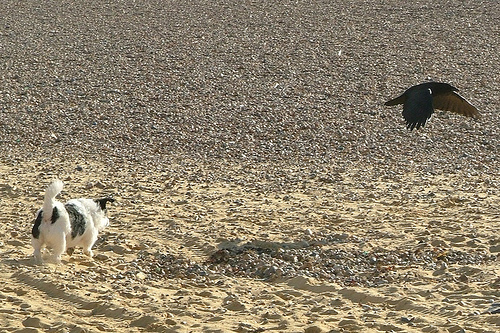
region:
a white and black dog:
[22, 160, 125, 270]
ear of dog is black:
[90, 185, 118, 215]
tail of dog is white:
[41, 165, 61, 221]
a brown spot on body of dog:
[61, 200, 91, 242]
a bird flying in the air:
[366, 69, 484, 141]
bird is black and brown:
[373, 73, 493, 139]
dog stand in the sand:
[10, 99, 267, 327]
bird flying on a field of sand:
[200, 15, 493, 284]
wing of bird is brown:
[426, 78, 486, 129]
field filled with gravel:
[12, 8, 404, 164]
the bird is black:
[374, 77, 495, 142]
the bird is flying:
[368, 70, 484, 134]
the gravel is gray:
[156, 47, 304, 138]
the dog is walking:
[30, 174, 120, 274]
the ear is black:
[94, 195, 117, 208]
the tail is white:
[41, 174, 65, 219]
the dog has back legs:
[28, 240, 67, 265]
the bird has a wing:
[443, 94, 488, 129]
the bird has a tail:
[375, 83, 406, 116]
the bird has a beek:
[452, 81, 461, 96]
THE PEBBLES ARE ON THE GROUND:
[1, 3, 497, 171]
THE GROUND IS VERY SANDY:
[1, 150, 498, 326]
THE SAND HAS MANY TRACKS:
[3, 150, 487, 332]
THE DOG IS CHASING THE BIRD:
[23, 162, 130, 279]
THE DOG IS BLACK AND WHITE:
[13, 175, 118, 270]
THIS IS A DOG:
[23, 170, 138, 282]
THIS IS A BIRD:
[374, 70, 486, 147]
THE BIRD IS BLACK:
[373, 80, 487, 138]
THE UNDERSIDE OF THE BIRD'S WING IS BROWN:
[427, 85, 489, 132]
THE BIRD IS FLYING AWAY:
[368, 60, 483, 150]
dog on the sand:
[18, 162, 141, 279]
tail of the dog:
[37, 161, 76, 208]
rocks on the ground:
[225, 224, 295, 279]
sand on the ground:
[181, 287, 266, 332]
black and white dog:
[4, 129, 154, 285]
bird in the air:
[386, 70, 478, 140]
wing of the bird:
[390, 96, 444, 137]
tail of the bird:
[371, 85, 414, 122]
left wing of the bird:
[458, 98, 488, 128]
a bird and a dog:
[0, 41, 478, 309]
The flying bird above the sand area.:
[382, 68, 479, 129]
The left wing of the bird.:
[405, 90, 432, 128]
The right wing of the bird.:
[431, 90, 475, 115]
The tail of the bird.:
[390, 93, 407, 109]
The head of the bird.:
[435, 81, 461, 98]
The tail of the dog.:
[41, 183, 58, 220]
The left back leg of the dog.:
[23, 242, 48, 269]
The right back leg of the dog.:
[48, 235, 65, 267]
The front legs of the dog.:
[67, 241, 100, 260]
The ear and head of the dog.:
[78, 178, 108, 219]